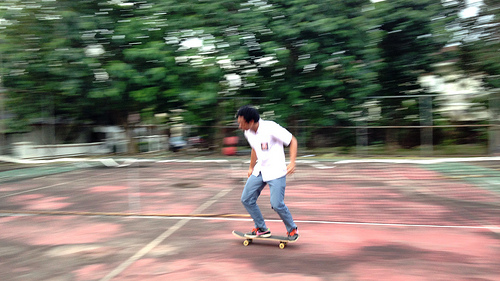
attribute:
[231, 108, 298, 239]
man — facing left, skateboarding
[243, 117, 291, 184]
shirt — white, collared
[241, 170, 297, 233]
pants — blue jeans, blue jean, blue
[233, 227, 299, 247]
skateboard — black, moving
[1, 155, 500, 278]
tennis court — red, white lined, flat, red colored, reddish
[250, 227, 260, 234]
laces — red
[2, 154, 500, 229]
tennis net — white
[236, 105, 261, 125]
hair — black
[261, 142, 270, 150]
logo — red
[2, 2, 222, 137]
tree — green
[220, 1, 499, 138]
tree — green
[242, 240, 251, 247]
wheel — yellow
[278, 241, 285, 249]
wheel — yellow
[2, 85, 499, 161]
wire fence — chain link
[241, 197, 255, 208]
knee — bended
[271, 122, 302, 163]
arm — bent